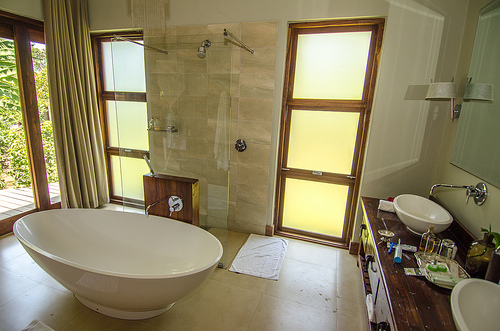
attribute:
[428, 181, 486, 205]
faucet — chrome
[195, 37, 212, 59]
shower head — silver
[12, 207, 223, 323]
bathtub — porcelain, white, free-standing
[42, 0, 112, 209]
curtain — hanging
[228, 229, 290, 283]
towel — white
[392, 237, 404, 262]
toothbrush — blue, white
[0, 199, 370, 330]
floor — beige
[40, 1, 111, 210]
drapes — yellow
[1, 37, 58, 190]
leaves — green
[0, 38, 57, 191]
bush — green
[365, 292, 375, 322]
rag — white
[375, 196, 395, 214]
rag — white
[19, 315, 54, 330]
towel — white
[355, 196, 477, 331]
vanity — wooden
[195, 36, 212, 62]
shower head — chrome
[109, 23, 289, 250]
enclosure — glass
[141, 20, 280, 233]
wall — stone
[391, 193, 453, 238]
sink — white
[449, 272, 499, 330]
sink — white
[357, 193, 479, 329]
counter — wooden